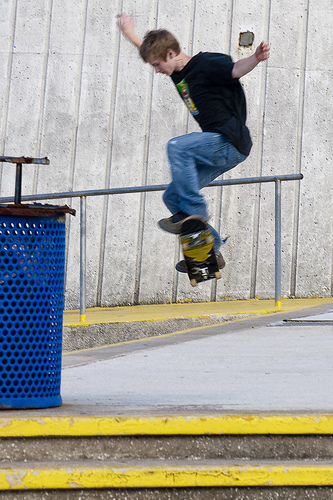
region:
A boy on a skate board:
[93, 13, 259, 311]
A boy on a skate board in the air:
[97, 17, 277, 318]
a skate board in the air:
[106, 168, 251, 308]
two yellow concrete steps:
[83, 387, 269, 494]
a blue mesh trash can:
[13, 195, 84, 411]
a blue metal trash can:
[8, 191, 90, 417]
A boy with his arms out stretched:
[83, 6, 297, 148]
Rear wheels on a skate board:
[168, 262, 241, 303]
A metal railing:
[68, 169, 162, 309]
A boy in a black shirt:
[107, 18, 291, 191]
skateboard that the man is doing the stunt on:
[174, 215, 229, 289]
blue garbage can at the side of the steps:
[1, 198, 73, 414]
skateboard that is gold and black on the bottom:
[166, 208, 226, 289]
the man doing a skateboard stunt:
[109, 8, 294, 267]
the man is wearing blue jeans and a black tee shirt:
[111, 12, 258, 271]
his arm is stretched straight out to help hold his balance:
[203, 35, 294, 84]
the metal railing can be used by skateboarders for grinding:
[4, 171, 307, 209]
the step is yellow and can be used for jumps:
[0, 416, 331, 457]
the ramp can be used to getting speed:
[0, 296, 303, 330]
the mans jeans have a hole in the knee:
[123, 126, 265, 266]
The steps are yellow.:
[0, 392, 330, 488]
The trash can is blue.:
[1, 193, 69, 410]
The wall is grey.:
[2, 1, 331, 260]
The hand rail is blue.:
[6, 163, 308, 300]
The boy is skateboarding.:
[106, 11, 265, 284]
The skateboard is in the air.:
[156, 195, 239, 293]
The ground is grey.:
[64, 301, 331, 410]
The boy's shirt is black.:
[129, 22, 264, 154]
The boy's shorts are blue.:
[155, 113, 241, 266]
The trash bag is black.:
[0, 189, 76, 220]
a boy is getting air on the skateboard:
[109, 12, 272, 287]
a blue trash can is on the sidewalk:
[0, 202, 68, 411]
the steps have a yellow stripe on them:
[3, 413, 330, 498]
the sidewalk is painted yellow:
[64, 295, 331, 318]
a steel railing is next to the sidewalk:
[11, 170, 305, 311]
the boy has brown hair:
[135, 27, 180, 65]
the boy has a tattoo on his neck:
[170, 53, 189, 72]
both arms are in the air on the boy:
[108, 9, 272, 98]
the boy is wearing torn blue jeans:
[161, 131, 249, 219]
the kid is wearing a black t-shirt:
[169, 48, 259, 155]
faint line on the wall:
[16, 45, 97, 64]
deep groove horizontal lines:
[46, 127, 170, 259]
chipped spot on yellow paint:
[39, 468, 96, 486]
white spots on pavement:
[151, 437, 202, 461]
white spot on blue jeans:
[156, 122, 197, 151]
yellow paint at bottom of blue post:
[265, 294, 298, 307]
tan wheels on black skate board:
[183, 274, 241, 288]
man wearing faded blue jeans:
[148, 124, 250, 205]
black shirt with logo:
[133, 53, 263, 150]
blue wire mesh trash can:
[8, 202, 89, 388]